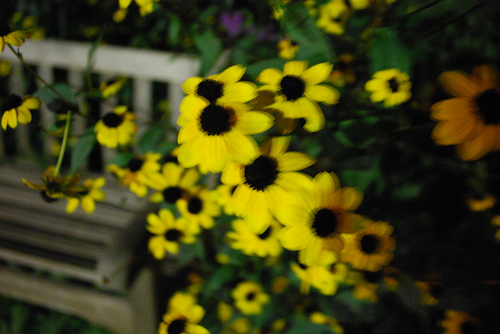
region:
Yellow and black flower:
[173, 93, 261, 165]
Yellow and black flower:
[233, 152, 303, 216]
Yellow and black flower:
[364, 75, 407, 109]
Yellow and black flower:
[424, 55, 499, 161]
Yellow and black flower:
[92, 101, 132, 140]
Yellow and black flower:
[97, 68, 126, 97]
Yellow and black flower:
[4, 83, 31, 132]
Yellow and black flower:
[29, 161, 90, 216]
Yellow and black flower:
[125, 208, 218, 269]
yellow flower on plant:
[182, 72, 262, 186]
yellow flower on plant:
[226, 138, 310, 248]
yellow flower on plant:
[187, 189, 234, 261]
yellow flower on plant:
[159, 159, 209, 211]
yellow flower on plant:
[122, 153, 164, 193]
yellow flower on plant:
[66, 163, 114, 218]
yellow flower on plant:
[30, 163, 82, 215]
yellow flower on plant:
[92, 102, 142, 156]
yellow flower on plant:
[3, 92, 44, 134]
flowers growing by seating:
[16, 10, 481, 320]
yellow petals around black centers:
[180, 96, 310, 236]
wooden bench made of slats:
[1, 31, 201, 326]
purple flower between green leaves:
[196, 6, 253, 36]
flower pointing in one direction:
[360, 62, 410, 104]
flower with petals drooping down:
[0, 80, 40, 130]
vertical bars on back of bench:
[0, 31, 200, 176]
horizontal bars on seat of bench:
[0, 155, 141, 295]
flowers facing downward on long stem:
[20, 105, 100, 211]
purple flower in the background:
[208, 6, 267, 41]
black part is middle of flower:
[101, 111, 123, 128]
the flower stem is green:
[50, 111, 71, 177]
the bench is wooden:
[7, 211, 139, 319]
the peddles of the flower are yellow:
[187, 136, 244, 173]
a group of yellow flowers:
[181, 77, 355, 262]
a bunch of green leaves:
[355, 131, 427, 191]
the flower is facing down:
[17, 165, 76, 206]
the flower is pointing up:
[92, 109, 132, 144]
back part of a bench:
[42, 41, 197, 137]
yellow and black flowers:
[105, 74, 410, 306]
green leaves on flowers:
[204, 0, 406, 300]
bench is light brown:
[12, 57, 214, 314]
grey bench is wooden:
[0, 65, 208, 319]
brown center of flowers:
[195, 75, 259, 163]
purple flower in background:
[200, 13, 271, 67]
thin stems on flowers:
[25, 67, 83, 188]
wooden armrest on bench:
[82, 154, 157, 304]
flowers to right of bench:
[180, 20, 468, 290]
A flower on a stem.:
[176, 185, 218, 234]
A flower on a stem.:
[129, 157, 203, 212]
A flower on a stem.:
[359, 69, 403, 110]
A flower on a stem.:
[343, 211, 401, 273]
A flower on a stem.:
[229, 282, 268, 313]